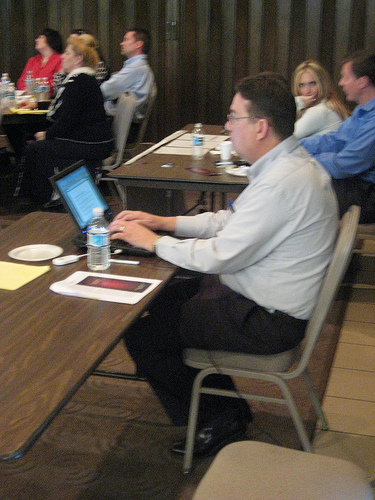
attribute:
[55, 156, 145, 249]
laptop — open, ibm, black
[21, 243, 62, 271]
plate — disposable, white, empty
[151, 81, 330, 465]
man — middle-aged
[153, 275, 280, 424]
pants — black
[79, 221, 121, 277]
bottle — plastic, clear, water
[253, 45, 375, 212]
people — in room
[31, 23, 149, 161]
people — watching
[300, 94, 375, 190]
shirt — blue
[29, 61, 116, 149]
sweater — black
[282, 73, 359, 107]
hair — blonde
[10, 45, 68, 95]
shirt — red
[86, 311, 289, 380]
floor — hardwood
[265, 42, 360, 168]
woman — looking forward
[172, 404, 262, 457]
shoes — shiny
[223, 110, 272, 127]
eyeglasses — pair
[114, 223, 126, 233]
ring — small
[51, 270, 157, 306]
paper — red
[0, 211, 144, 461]
table — brown, wooden